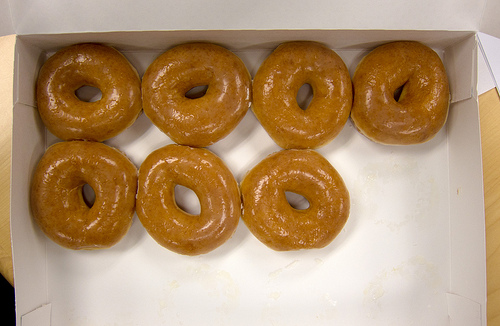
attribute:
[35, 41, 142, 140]
doughnut — glazed, round, brown, shiny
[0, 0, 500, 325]
box — white, square, open, clean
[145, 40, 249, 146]
doughnut — glazed, round, brown, shiny, oily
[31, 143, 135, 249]
doughnut — glazed, round, brown, shiny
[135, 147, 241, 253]
doughnut — glazed, round, brown, shiny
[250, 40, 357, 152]
doughnut — glazed, round, brown, shiny, grouped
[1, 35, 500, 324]
table — light colored, brown, wooden